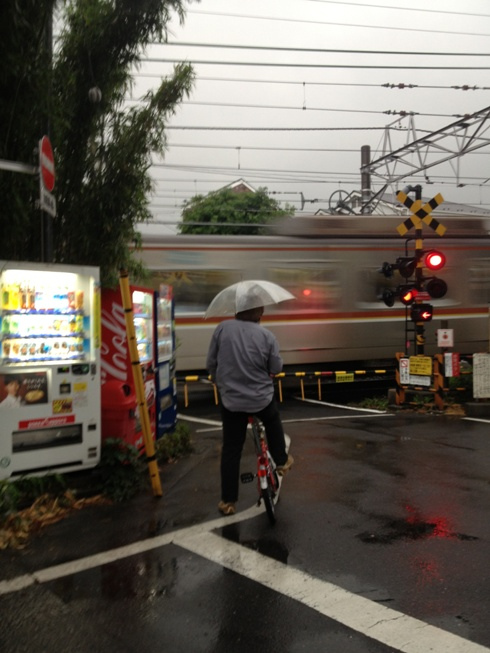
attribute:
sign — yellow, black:
[390, 186, 448, 239]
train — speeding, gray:
[103, 211, 488, 381]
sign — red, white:
[17, 120, 88, 227]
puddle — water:
[353, 505, 480, 547]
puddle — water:
[329, 417, 425, 484]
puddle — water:
[75, 540, 389, 632]